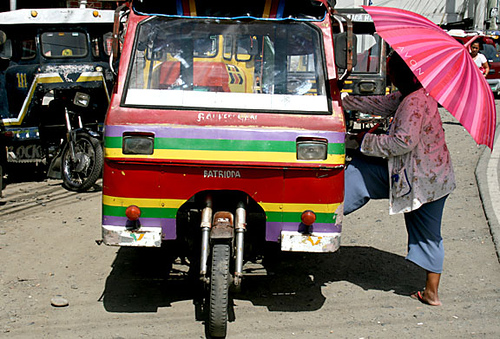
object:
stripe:
[125, 88, 326, 115]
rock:
[50, 294, 69, 307]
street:
[17, 211, 87, 298]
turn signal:
[300, 209, 316, 226]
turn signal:
[124, 204, 142, 220]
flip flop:
[410, 289, 444, 308]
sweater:
[339, 85, 456, 217]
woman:
[342, 52, 455, 305]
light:
[92, 10, 100, 16]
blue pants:
[339, 155, 450, 277]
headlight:
[120, 136, 153, 156]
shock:
[229, 195, 248, 287]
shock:
[198, 191, 215, 281]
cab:
[97, 0, 350, 338]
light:
[117, 128, 160, 163]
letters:
[396, 46, 405, 51]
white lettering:
[203, 169, 208, 178]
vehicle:
[90, 0, 357, 330]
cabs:
[0, 0, 115, 190]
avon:
[396, 46, 425, 76]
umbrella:
[354, 3, 495, 154]